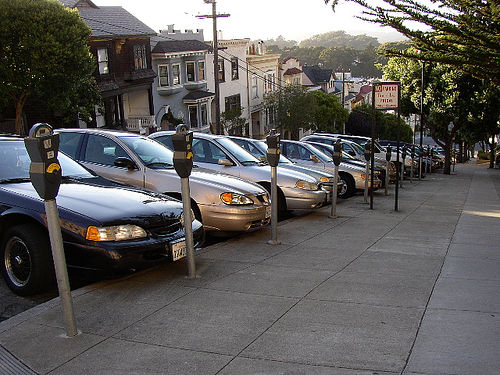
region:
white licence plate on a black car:
[171, 238, 190, 259]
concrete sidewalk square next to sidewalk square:
[108, 285, 303, 357]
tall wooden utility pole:
[193, 0, 234, 135]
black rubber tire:
[3, 215, 54, 297]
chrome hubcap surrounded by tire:
[4, 235, 33, 287]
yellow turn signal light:
[87, 225, 97, 240]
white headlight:
[98, 223, 145, 242]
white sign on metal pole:
[368, 80, 399, 207]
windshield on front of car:
[214, 135, 259, 166]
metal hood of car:
[5, 177, 191, 229]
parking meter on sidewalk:
[173, 119, 223, 284]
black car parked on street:
[1, 135, 195, 275]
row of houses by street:
[54, 1, 356, 127]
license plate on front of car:
[170, 237, 200, 260]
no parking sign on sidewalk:
[368, 67, 416, 145]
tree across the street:
[0, 1, 85, 112]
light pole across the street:
[198, 2, 235, 129]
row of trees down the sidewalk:
[446, 0, 498, 177]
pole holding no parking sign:
[371, 117, 403, 211]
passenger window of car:
[88, 135, 133, 172]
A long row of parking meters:
[1, 120, 471, 335]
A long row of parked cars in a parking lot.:
[1, 130, 456, 287]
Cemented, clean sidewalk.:
[0, 162, 496, 373]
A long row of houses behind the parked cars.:
[1, 2, 423, 138]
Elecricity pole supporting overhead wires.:
[200, 1, 230, 133]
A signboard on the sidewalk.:
[372, 83, 399, 108]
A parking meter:
[22, 123, 59, 201]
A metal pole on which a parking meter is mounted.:
[44, 200, 78, 337]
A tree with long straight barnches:
[320, 2, 499, 66]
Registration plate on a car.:
[170, 238, 187, 260]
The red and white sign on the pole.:
[375, 83, 397, 109]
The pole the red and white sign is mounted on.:
[371, 78, 378, 220]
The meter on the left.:
[15, 115, 90, 342]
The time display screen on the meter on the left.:
[38, 128, 47, 132]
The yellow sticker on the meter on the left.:
[43, 160, 61, 174]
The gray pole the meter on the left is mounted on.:
[44, 196, 81, 335]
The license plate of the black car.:
[160, 236, 193, 261]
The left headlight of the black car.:
[82, 223, 142, 238]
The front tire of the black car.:
[6, 218, 52, 289]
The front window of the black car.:
[1, 140, 91, 181]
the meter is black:
[20, 113, 64, 200]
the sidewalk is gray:
[290, 237, 365, 352]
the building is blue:
[148, 30, 221, 130]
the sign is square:
[357, 79, 412, 111]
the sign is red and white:
[373, 80, 404, 113]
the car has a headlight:
[218, 182, 257, 217]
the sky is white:
[267, 6, 312, 24]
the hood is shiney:
[92, 177, 134, 217]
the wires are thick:
[231, 51, 274, 84]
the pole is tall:
[192, 2, 231, 123]